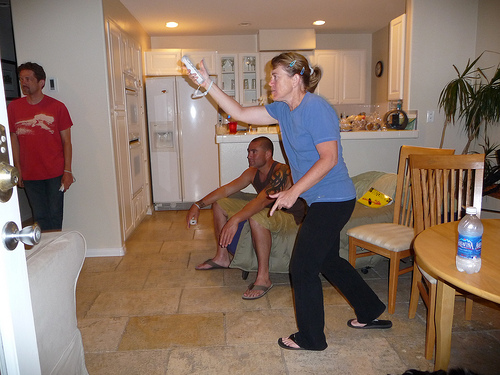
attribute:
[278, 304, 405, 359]
shoes — black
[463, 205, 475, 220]
white top — bottle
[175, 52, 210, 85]
control — up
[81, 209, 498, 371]
floor — brown, stone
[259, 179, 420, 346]
pants — black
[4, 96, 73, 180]
shirt — red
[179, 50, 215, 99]
controller — gaming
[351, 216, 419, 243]
seat — white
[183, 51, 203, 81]
remote — white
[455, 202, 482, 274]
can — water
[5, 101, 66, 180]
t-shirt — red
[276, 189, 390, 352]
pants — black